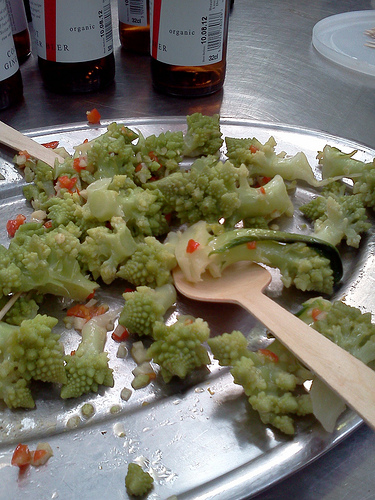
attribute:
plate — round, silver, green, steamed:
[2, 119, 373, 497]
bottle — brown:
[0, 9, 225, 98]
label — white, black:
[4, 1, 236, 67]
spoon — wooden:
[161, 234, 374, 424]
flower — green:
[6, 114, 373, 433]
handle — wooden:
[245, 298, 374, 411]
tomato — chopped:
[35, 109, 107, 183]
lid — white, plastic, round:
[311, 1, 374, 81]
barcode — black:
[94, 10, 115, 40]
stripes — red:
[33, 0, 164, 64]